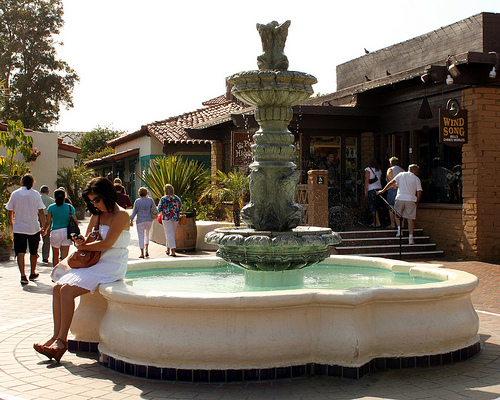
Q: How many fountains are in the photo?
A: One.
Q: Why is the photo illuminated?
A: Sunlight.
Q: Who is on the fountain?
A: The woman.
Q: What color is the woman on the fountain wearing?
A: White.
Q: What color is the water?
A: Blue.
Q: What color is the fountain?
A: Cream.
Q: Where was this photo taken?
A: On the sidewalk.